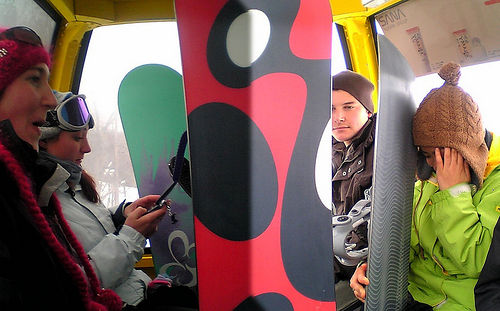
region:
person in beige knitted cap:
[423, 63, 482, 170]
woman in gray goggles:
[61, 88, 98, 152]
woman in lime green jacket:
[424, 205, 454, 259]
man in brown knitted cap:
[341, 78, 382, 114]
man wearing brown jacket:
[351, 148, 354, 166]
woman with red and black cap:
[16, 28, 35, 29]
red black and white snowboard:
[206, 55, 286, 220]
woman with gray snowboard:
[370, 192, 401, 262]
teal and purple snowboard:
[138, 100, 164, 161]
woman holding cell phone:
[151, 182, 171, 228]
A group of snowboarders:
[9, 3, 486, 291]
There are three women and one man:
[11, 14, 476, 293]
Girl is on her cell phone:
[123, 175, 187, 230]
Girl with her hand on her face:
[413, 73, 490, 200]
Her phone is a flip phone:
[124, 171, 178, 230]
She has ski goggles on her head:
[50, 86, 106, 146]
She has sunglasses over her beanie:
[4, 18, 49, 73]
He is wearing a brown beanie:
[331, 65, 383, 117]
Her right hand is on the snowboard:
[341, 24, 452, 309]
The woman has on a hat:
[1, 13, 59, 120]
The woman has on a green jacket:
[396, 170, 498, 302]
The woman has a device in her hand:
[116, 165, 194, 245]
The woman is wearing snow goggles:
[53, 90, 100, 135]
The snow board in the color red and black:
[165, 10, 367, 305]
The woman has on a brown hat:
[410, 65, 488, 191]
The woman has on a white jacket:
[49, 166, 172, 303]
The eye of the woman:
[23, 68, 47, 92]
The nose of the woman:
[38, 80, 60, 110]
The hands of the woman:
[121, 190, 174, 237]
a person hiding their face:
[409, 60, 494, 207]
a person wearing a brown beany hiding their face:
[408, 53, 496, 203]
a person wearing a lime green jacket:
[411, 56, 495, 309]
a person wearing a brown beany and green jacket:
[411, 55, 495, 299]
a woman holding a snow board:
[360, 10, 488, 300]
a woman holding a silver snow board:
[355, 5, 490, 300]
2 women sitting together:
[0, 19, 118, 299]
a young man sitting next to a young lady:
[330, 66, 498, 302]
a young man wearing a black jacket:
[331, 64, 372, 272]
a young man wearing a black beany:
[331, 67, 375, 282]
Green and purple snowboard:
[116, 61, 196, 282]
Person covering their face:
[394, 61, 499, 308]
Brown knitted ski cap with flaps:
[412, 66, 488, 184]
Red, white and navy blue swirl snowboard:
[191, 0, 335, 305]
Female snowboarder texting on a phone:
[31, 88, 176, 308]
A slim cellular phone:
[153, 178, 180, 204]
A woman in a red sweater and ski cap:
[1, 20, 111, 306]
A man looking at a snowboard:
[331, 69, 377, 214]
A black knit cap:
[332, 70, 373, 113]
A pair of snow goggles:
[36, 91, 93, 133]